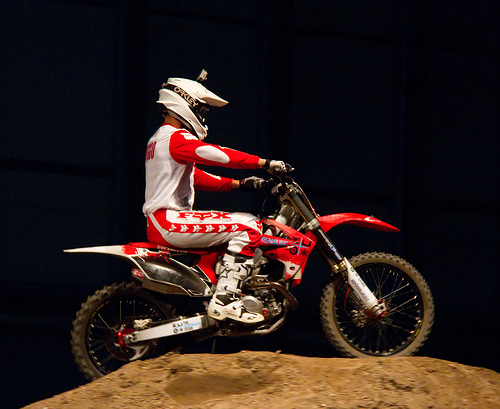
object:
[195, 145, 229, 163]
patch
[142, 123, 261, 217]
shirt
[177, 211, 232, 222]
fox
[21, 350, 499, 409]
dirt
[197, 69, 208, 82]
camera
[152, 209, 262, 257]
red stripe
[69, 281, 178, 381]
tire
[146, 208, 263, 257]
pants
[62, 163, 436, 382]
bike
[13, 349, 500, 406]
hill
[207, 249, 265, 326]
boot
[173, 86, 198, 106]
logo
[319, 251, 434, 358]
tire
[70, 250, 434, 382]
two wheels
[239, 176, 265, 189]
glove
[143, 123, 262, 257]
suit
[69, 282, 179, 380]
wheel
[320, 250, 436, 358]
wheel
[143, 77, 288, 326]
rider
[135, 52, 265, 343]
rider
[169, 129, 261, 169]
sleeve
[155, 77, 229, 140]
helmet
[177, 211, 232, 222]
word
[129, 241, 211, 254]
seat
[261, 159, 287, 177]
glove